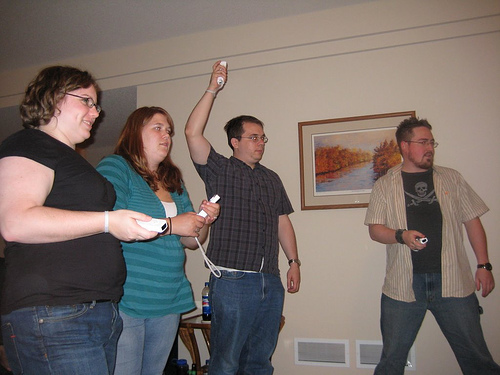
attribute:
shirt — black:
[362, 160, 488, 306]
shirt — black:
[201, 145, 293, 277]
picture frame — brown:
[296, 109, 419, 212]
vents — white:
[281, 330, 419, 371]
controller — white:
[404, 226, 429, 251]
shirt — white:
[154, 186, 191, 226]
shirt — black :
[1, 126, 132, 307]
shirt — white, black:
[394, 173, 447, 271]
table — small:
[176, 307, 286, 373]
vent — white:
[290, 337, 350, 367]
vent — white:
[354, 339, 415, 369]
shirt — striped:
[92, 151, 208, 315]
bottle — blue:
[195, 273, 213, 319]